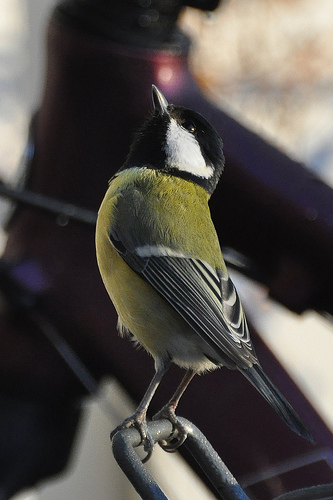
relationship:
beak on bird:
[151, 84, 170, 115] [95, 84, 315, 498]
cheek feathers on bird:
[162, 116, 216, 183] [64, 56, 311, 487]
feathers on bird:
[94, 165, 318, 464] [103, 81, 319, 453]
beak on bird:
[151, 84, 170, 115] [103, 81, 319, 453]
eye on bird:
[183, 123, 195, 132] [74, 75, 320, 463]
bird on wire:
[103, 81, 319, 453] [109, 412, 251, 499]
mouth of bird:
[128, 60, 185, 118] [61, 80, 242, 304]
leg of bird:
[108, 360, 167, 463] [103, 81, 319, 453]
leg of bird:
[140, 370, 194, 454] [103, 81, 319, 453]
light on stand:
[184, 420, 196, 434] [100, 393, 262, 491]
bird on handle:
[94, 81, 319, 465] [122, 387, 210, 493]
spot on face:
[163, 117, 213, 179] [117, 82, 219, 169]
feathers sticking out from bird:
[94, 165, 318, 464] [93, 49, 250, 367]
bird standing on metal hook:
[103, 81, 319, 453] [110, 415, 248, 497]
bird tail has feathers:
[230, 349, 332, 449] [211, 311, 328, 463]